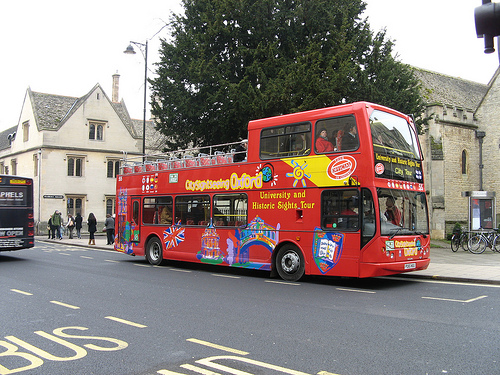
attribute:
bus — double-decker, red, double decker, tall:
[114, 101, 433, 284]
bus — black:
[0, 175, 34, 251]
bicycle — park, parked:
[469, 231, 499, 252]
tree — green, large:
[151, 4, 433, 113]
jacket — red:
[317, 137, 333, 151]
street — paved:
[2, 283, 500, 374]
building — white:
[19, 91, 128, 246]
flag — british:
[155, 229, 189, 247]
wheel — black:
[271, 245, 307, 282]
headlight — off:
[395, 249, 405, 259]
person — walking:
[49, 211, 65, 239]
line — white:
[51, 296, 81, 314]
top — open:
[117, 130, 247, 172]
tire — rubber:
[146, 234, 163, 265]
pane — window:
[315, 115, 357, 153]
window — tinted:
[325, 191, 358, 229]